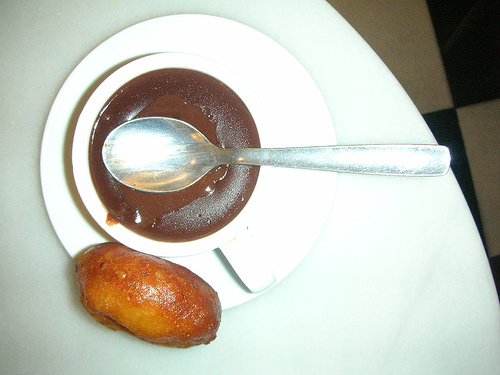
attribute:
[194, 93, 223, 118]
sauce — brown, chocolate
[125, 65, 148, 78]
bowl — white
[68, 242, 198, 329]
pastry — brown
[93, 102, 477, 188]
spoon — silver, metal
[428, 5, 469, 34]
floor — white, checkered, black, tiled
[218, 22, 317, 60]
plate — white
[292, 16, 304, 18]
table — round, white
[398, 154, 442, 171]
reflection — light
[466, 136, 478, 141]
tiles — white, black